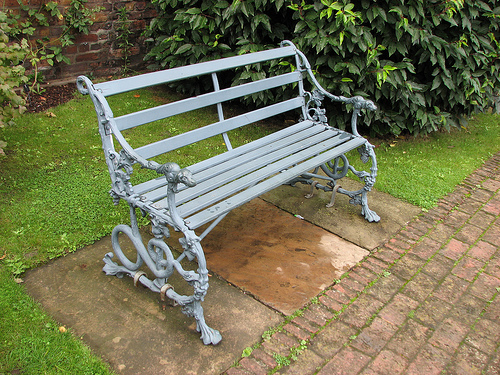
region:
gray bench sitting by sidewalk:
[89, 44, 384, 319]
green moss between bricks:
[309, 291, 359, 338]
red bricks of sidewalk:
[378, 212, 494, 363]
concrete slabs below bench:
[56, 246, 237, 366]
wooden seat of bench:
[192, 110, 330, 225]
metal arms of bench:
[68, 104, 218, 304]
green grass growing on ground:
[34, 129, 127, 215]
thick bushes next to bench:
[200, 14, 467, 116]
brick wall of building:
[1, 6, 138, 75]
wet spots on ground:
[202, 208, 319, 296]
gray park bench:
[77, 37, 388, 347]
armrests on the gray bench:
[94, 79, 379, 202]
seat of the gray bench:
[124, 122, 346, 233]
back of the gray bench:
[100, 46, 304, 169]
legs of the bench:
[99, 145, 376, 347]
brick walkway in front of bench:
[228, 152, 497, 368]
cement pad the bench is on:
[25, 167, 419, 374]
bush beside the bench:
[122, 2, 499, 136]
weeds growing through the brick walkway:
[244, 180, 499, 371]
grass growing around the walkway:
[0, 77, 497, 374]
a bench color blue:
[50, 35, 388, 345]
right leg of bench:
[324, 158, 392, 233]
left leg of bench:
[92, 228, 229, 358]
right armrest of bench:
[310, 75, 384, 137]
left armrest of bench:
[104, 126, 209, 240]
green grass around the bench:
[8, 29, 440, 369]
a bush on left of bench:
[34, 1, 492, 313]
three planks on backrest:
[80, 38, 317, 162]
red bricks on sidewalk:
[261, 181, 498, 373]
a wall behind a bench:
[4, 6, 384, 351]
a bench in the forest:
[47, 50, 469, 309]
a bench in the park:
[52, 37, 447, 369]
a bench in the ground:
[50, 25, 436, 370]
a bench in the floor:
[32, 40, 472, 368]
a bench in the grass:
[65, 22, 497, 294]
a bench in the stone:
[61, 31, 441, 361]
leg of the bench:
[74, 188, 252, 374]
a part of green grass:
[229, 312, 341, 372]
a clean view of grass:
[19, 73, 470, 221]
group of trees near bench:
[306, 10, 498, 114]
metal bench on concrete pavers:
[51, 44, 418, 357]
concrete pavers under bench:
[13, 172, 420, 373]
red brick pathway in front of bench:
[384, 244, 476, 354]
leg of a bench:
[187, 241, 224, 359]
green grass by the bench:
[17, 117, 94, 237]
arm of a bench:
[89, 96, 198, 207]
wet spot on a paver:
[258, 236, 318, 287]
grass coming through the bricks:
[254, 319, 315, 371]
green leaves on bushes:
[339, 1, 453, 93]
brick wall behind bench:
[50, 2, 139, 98]